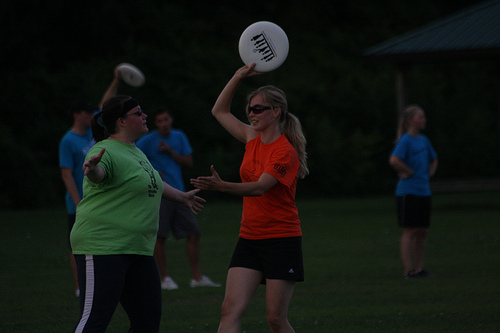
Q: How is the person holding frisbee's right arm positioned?
A: Upward and bent.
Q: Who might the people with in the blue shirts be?
A: Members of frisbee team.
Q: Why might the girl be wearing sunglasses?
A: To block sun's glare.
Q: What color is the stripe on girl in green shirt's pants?
A: White.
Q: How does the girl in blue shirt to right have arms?
A: On hips.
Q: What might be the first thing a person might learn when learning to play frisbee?
A: Throwing.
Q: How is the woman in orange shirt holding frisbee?
A: Above head.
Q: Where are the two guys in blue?
A: Behind the person in green.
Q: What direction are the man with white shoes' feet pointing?
A: His left.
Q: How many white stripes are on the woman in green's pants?
A: One.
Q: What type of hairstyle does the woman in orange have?
A: A ponytail.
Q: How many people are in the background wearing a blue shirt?
A: Three.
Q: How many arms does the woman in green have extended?
A: Two.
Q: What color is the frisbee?
A: White.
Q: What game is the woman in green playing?
A: Frisbee.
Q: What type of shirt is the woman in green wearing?
A: A T-shirt.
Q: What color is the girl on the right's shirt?
A: Blue.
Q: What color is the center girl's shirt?
A: Orange.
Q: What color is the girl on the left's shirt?
A: Green.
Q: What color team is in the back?
A: Blue.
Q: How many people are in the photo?
A: 5.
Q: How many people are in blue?
A: 3.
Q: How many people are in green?
A: 1.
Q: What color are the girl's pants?
A: Black.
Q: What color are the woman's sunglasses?
A: Black.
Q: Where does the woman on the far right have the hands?
A: On her hips.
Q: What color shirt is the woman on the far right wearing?
A: Blue.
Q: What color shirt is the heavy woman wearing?
A: Green.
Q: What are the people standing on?
A: Grass.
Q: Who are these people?
A: Women.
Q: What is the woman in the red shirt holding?
A: Frisbee.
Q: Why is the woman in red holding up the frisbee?
A: Different teams.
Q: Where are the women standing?
A: Grass field.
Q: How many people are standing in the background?
A: Three.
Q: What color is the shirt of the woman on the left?
A: Green.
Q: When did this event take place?
A: Evening.